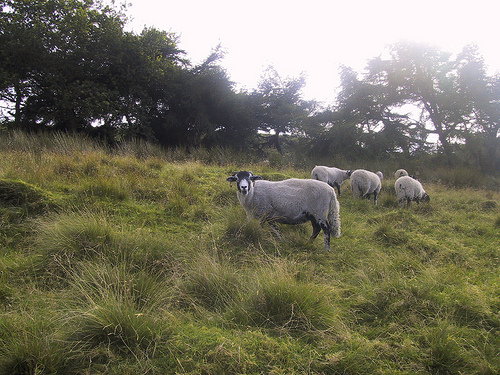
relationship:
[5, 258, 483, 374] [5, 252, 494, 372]
grass on weeds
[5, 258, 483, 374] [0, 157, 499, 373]
grass on land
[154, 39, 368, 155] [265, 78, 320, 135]
trees with leaves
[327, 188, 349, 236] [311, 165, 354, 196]
tail of sheep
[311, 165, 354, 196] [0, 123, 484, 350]
sheep on grass